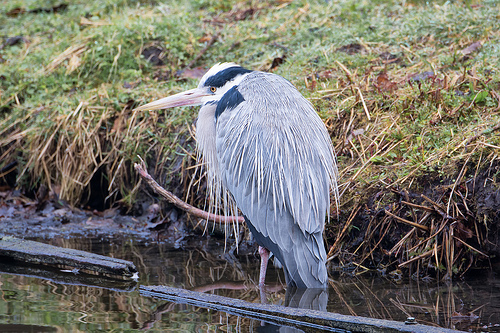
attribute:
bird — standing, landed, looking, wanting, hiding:
[167, 87, 363, 311]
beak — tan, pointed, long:
[143, 84, 204, 110]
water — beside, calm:
[65, 210, 170, 263]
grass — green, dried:
[57, 30, 144, 148]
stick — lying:
[72, 248, 238, 330]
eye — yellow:
[205, 83, 235, 100]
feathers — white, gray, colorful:
[181, 150, 245, 231]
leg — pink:
[140, 167, 243, 253]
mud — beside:
[101, 180, 162, 240]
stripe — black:
[188, 58, 271, 96]